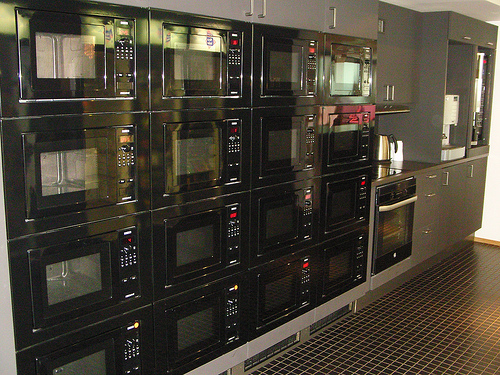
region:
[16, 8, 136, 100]
black colored microwave oven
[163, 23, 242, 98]
black colored microwave oven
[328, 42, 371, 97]
black colored microwave oven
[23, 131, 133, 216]
black colored microwave oven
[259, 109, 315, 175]
black colored microwave oven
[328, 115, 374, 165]
black colored microwave oven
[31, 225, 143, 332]
black colored microwave oven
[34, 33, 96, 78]
clear glass on microwave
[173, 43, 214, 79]
clear glass on microwave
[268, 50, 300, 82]
clear glass on microwave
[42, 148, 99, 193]
clear glass on microwave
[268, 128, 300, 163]
clear glass on microwave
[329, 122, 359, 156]
clear glass on microwave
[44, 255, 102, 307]
clear glass on microwave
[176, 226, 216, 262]
clear glass on microwave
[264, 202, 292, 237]
clear glass on microwave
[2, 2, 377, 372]
A bunch of microwaves.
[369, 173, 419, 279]
An oven in a cabinet.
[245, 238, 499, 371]
A black tile floor.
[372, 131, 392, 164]
A coffee pot on a counter.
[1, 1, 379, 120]
A row of microwaves.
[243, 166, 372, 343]
Four microwaves on a wall.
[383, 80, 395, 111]
A glass on a shelf.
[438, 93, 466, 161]
A white coffee maker.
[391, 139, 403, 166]
Paper cups on a shelf.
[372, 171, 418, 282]
a black kitchen oven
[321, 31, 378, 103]
a black microwave on a wall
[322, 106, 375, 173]
a black microwave on a wall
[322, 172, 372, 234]
a black microwave on a wall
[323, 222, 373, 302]
a black microwave on a wall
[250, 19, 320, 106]
a black microwave on a wall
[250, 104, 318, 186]
a black microwave on a wall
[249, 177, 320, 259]
a black microwave on a wall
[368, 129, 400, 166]
a metal coffee pot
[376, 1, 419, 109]
a grey cabinet door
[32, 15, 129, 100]
black microwave on display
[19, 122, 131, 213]
black microwave on display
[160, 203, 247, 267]
black microwave on display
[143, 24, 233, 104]
black microwave on display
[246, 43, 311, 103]
black microwave on display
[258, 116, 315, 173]
black microwave on display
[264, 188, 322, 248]
black microwave on display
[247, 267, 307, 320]
black microwave on display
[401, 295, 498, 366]
Tile floor is visible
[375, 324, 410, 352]
Black tile floor is visible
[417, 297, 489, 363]
Black and white tiles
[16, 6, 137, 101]
Microwave on the wall.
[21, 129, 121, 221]
Microwave on the wall.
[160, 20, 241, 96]
Microwave on the wall.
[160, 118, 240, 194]
Microwave on the wall.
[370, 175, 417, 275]
Stove on the wall.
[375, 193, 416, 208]
White handle on the stove.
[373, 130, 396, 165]
Coffee pot on the counter.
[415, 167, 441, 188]
Drawer on the wall.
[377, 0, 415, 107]
Cabinets above the stove.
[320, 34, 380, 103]
microwave is in the wall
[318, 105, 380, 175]
microwave is in the wall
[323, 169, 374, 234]
microwave is in the wall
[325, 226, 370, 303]
microwave is in the wall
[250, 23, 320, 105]
microwave is in the wall